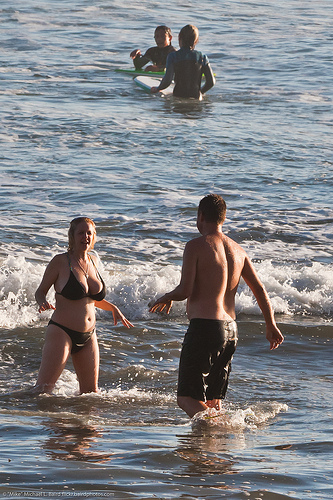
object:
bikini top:
[53, 252, 107, 299]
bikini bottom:
[47, 320, 97, 353]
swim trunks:
[176, 318, 238, 397]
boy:
[149, 24, 215, 98]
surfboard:
[134, 75, 175, 96]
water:
[2, 1, 332, 498]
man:
[150, 195, 284, 418]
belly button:
[88, 318, 92, 321]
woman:
[34, 217, 135, 398]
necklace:
[71, 250, 91, 277]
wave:
[5, 249, 332, 328]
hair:
[68, 216, 96, 250]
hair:
[197, 195, 226, 224]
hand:
[266, 327, 283, 352]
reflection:
[40, 415, 123, 465]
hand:
[112, 305, 134, 329]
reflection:
[172, 419, 247, 474]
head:
[67, 218, 96, 251]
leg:
[34, 323, 73, 391]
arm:
[35, 255, 59, 314]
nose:
[83, 233, 89, 240]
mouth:
[82, 239, 91, 244]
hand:
[147, 293, 172, 314]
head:
[197, 194, 227, 234]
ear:
[198, 210, 203, 220]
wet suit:
[161, 47, 216, 95]